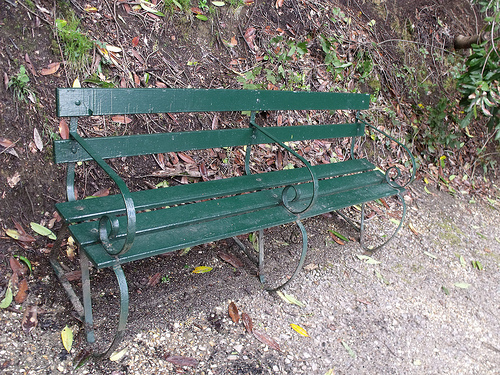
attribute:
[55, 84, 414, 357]
bench — green, outdoor, metal, dark green, park bench, wooden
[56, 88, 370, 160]
back — wooden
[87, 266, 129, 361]
support — curved, filigree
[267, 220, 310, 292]
support — curved, filigree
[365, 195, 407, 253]
support — curved, filigree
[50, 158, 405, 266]
seat — wooden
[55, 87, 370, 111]
rail — green, wooden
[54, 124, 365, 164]
rail — green, wooden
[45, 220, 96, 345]
support — rusted, metal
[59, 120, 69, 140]
leaf — dry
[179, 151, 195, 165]
leaf — dry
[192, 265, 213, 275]
leaf — yellow, bright, small, green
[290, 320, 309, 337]
leaf — small, yellow, soft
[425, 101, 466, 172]
plant — green, growing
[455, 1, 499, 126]
branch — leafy, green, low hanging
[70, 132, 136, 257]
armrest — curled, filigree, green, left armrest, metal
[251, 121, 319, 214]
armrest — curled, filigree, green, center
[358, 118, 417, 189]
armrest — curled, filigree, green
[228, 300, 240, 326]
leaf — brown, dry, brow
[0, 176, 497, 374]
ground — gravel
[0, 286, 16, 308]
leaf — green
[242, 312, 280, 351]
leaf — dry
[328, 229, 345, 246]
leaf — dry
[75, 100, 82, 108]
bolt — green, metal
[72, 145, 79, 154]
bolt — metal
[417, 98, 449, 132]
grass — green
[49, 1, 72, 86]
twig — brown